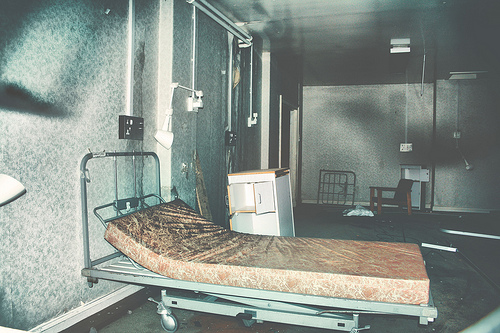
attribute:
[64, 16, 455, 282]
room — hospital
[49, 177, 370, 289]
mattress — curled, folded, propped, metallic, colored, empty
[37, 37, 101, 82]
wallpaper — floral, green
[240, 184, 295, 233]
cabinet — slanted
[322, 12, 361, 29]
ceiling — shiny, green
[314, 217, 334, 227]
floor — dark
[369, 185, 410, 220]
chair — wood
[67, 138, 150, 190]
frame — metal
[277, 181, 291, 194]
fridge — white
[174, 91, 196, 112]
globe — white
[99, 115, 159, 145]
socket — black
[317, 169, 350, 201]
table — folded